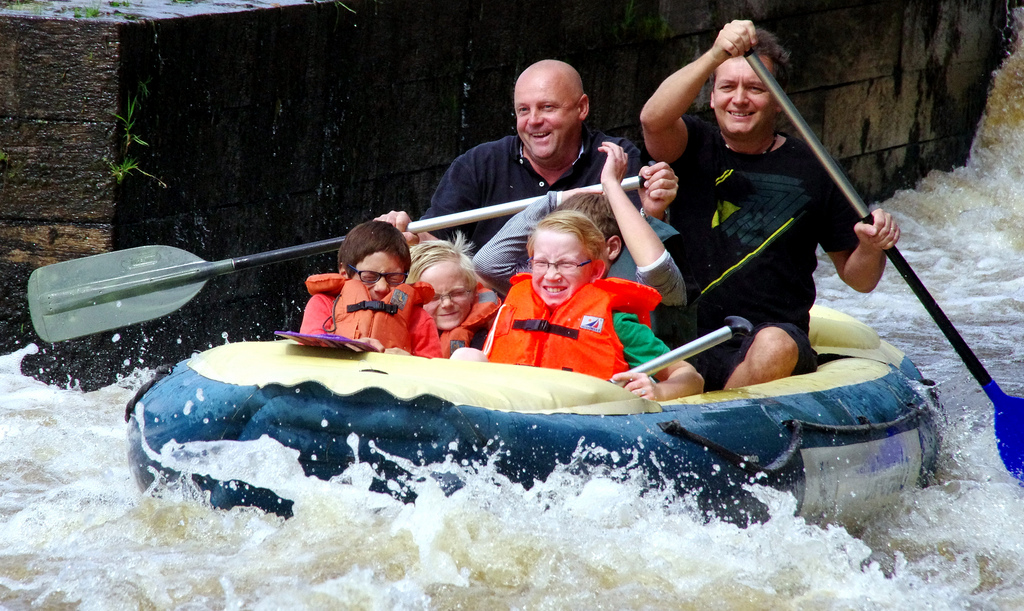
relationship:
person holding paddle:
[378, 56, 679, 252] [27, 176, 644, 344]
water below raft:
[1, 162, 1023, 609] [125, 301, 947, 539]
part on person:
[501, 57, 590, 167] [367, 56, 677, 253]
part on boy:
[333, 218, 400, 299] [298, 220, 445, 358]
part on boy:
[409, 237, 480, 336] [406, 230, 501, 362]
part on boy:
[531, 215, 602, 307] [484, 209, 708, 404]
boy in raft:
[484, 209, 708, 404] [125, 301, 947, 539]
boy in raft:
[484, 209, 708, 404] [115, 334, 949, 535]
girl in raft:
[466, 140, 687, 342] [115, 334, 949, 535]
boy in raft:
[406, 230, 501, 362] [115, 334, 949, 535]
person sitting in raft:
[378, 56, 679, 252] [115, 334, 949, 535]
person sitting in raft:
[637, 15, 904, 393] [115, 334, 949, 535]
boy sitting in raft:
[298, 220, 445, 358] [115, 334, 949, 535]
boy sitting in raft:
[406, 230, 501, 362] [115, 334, 949, 535]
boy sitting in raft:
[484, 209, 708, 404] [121, 333, 944, 556]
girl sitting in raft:
[466, 140, 687, 342] [115, 334, 949, 535]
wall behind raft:
[1, 1, 1007, 353] [125, 301, 947, 539]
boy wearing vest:
[302, 217, 443, 357] [304, 271, 435, 348]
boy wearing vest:
[406, 232, 501, 362] [435, 291, 500, 356]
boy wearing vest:
[483, 209, 706, 406] [489, 269, 660, 377]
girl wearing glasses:
[489, 209, 705, 405] [530, 255, 600, 271]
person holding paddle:
[637, 15, 904, 393] [741, 37, 1023, 483]